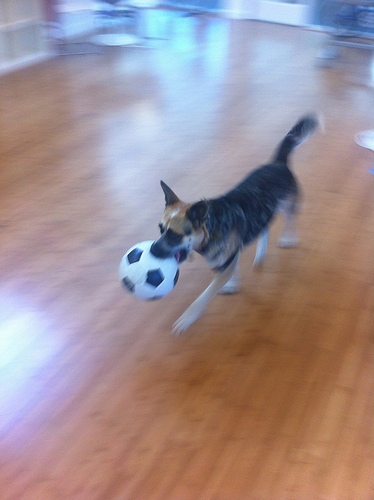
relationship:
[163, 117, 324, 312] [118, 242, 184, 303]
dog holding soccer ball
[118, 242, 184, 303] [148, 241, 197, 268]
soccer ball in mouth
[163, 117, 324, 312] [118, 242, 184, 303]
dog carrying soccer ball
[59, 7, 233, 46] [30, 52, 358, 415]
light shining on floor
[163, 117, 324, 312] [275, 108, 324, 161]
dog has tail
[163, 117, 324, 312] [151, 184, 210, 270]
dog has head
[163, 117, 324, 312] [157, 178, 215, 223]
dog has ears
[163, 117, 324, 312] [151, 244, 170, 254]
dog has snout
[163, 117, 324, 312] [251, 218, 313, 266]
dog has legs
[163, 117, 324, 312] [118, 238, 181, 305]
dog has soccer ball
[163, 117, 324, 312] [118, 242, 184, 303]
dog playing with soccer ball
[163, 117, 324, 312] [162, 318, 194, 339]
dog has front paw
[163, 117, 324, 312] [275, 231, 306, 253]
dog has rear paw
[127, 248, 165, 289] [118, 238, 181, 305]
pentagons ao soccer ball